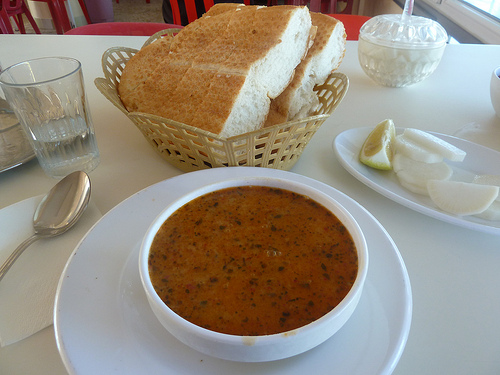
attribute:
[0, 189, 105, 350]
napkin — white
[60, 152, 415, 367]
plate — white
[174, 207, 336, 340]
soup — orange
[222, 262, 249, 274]
seasonings — green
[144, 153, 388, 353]
bowl — white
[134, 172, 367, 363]
bowl — white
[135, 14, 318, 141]
bread — french, cut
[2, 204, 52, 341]
napkin — white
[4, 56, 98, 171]
cup — glass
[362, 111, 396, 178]
lemon — slice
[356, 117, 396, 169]
lemon — wedge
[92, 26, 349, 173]
basket — full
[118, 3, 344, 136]
bread — white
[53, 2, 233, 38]
chair — red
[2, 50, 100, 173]
glass — clear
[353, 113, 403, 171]
slice — yellow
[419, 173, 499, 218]
slice — white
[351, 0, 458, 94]
container — glass, round